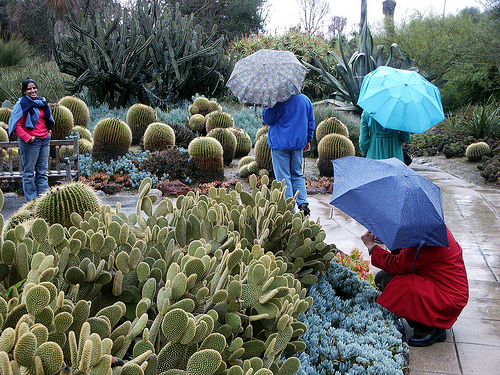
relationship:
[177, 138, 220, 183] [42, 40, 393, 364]
cactus in garden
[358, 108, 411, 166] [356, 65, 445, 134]
person in light-blue umbrella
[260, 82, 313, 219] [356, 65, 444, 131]
person in umbrella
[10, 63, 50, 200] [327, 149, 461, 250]
woman in blue umbrella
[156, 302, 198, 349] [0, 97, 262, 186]
cactus in garden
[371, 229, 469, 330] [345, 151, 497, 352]
coat on woman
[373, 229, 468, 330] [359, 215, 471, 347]
coat on person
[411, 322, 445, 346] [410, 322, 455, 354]
shoe on foot